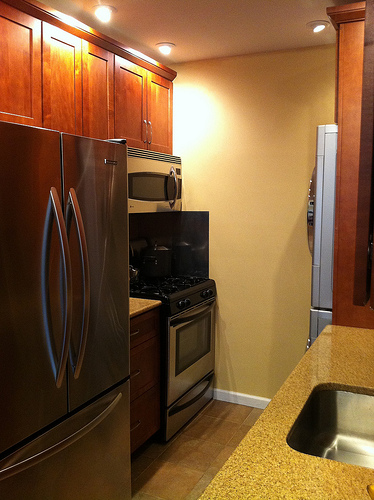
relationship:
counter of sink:
[211, 326, 373, 499] [293, 380, 373, 472]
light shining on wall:
[176, 82, 236, 165] [175, 60, 317, 387]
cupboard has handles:
[117, 55, 173, 154] [142, 118, 156, 143]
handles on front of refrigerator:
[46, 186, 86, 392] [0, 122, 130, 495]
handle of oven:
[166, 298, 221, 328] [146, 270, 226, 430]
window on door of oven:
[178, 323, 212, 365] [146, 270, 226, 430]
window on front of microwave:
[133, 171, 172, 200] [124, 149, 186, 214]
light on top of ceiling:
[91, 5, 120, 25] [57, 3, 337, 60]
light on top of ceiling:
[155, 38, 176, 56] [57, 3, 337, 60]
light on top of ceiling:
[309, 21, 328, 34] [57, 3, 337, 60]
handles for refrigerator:
[46, 186, 86, 392] [0, 122, 130, 495]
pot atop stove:
[140, 245, 169, 276] [135, 273, 200, 296]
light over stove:
[91, 5, 120, 25] [135, 273, 200, 296]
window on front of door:
[178, 323, 212, 365] [170, 312, 216, 382]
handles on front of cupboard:
[142, 118, 156, 143] [117, 55, 173, 154]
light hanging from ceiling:
[91, 5, 120, 25] [57, 3, 337, 60]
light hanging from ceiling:
[155, 38, 176, 56] [57, 3, 337, 60]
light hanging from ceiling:
[309, 21, 328, 34] [57, 3, 337, 60]